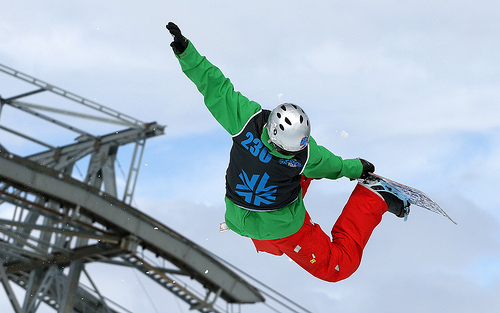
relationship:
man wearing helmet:
[164, 22, 409, 282] [262, 100, 311, 152]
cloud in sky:
[0, 0, 497, 313] [0, 1, 498, 311]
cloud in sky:
[2, 1, 497, 171] [0, 1, 498, 311]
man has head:
[164, 22, 409, 282] [267, 105, 314, 156]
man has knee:
[164, 22, 409, 282] [303, 251, 363, 286]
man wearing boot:
[164, 22, 409, 282] [364, 178, 410, 219]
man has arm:
[164, 22, 409, 282] [128, 11, 278, 147]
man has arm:
[164, 22, 409, 282] [298, 140, 377, 183]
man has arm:
[164, 22, 409, 282] [164, 20, 264, 140]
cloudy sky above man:
[1, 5, 499, 308] [164, 22, 409, 282]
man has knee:
[164, 22, 409, 282] [314, 245, 353, 283]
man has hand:
[164, 22, 409, 282] [345, 150, 381, 177]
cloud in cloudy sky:
[0, 0, 497, 313] [0, 0, 499, 313]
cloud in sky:
[0, 0, 497, 313] [330, 17, 453, 122]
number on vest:
[239, 128, 270, 165] [218, 132, 325, 217]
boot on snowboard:
[356, 170, 413, 222] [347, 163, 459, 228]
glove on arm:
[148, 16, 185, 61] [113, 42, 244, 130]